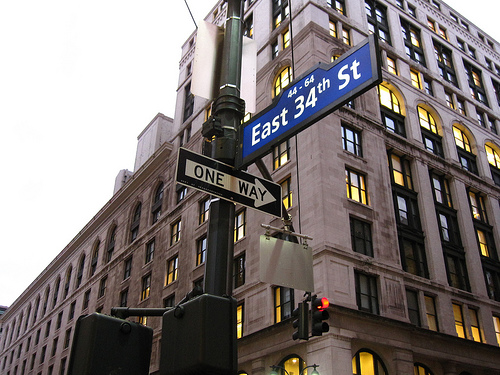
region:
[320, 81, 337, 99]
the sign is blue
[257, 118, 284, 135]
the word is white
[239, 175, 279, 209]
the arrow is white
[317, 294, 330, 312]
the light is red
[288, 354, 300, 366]
the light is on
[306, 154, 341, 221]
the building is tan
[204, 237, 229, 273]
the pole is black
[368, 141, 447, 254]
the building has a lot of windows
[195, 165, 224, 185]
the word is black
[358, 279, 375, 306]
the blind is closed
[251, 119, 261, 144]
white letter on sign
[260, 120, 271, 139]
white letter on sign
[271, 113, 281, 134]
white letter on sign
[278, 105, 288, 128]
white letter on sign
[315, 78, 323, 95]
white letter on sign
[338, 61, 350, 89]
white letter on sign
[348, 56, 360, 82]
white letter on sign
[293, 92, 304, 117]
white number on sign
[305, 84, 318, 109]
white number on sign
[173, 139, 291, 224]
The sign is black and white.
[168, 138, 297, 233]
The arrow on the sign is white.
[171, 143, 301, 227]
The sign is rectangulare.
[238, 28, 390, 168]
The sign is blue and white.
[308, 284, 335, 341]
The traffic light is red.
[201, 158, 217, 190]
The letter is black.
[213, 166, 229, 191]
The letter is black.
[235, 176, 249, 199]
The letter is black.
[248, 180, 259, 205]
The letter is black.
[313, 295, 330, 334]
traffic light on the wire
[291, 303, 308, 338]
traffic light on the wire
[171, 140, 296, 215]
traffic sign on the pole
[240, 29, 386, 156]
street sign on the pole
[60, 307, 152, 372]
back of the crosswalk light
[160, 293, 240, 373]
back of the cross walk light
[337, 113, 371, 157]
window on the buiding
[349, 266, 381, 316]
window on the buiding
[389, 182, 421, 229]
window on the buiding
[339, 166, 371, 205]
a window on building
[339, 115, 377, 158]
a window on building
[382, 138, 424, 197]
a window on building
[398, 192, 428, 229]
a window on building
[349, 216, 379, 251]
a window on building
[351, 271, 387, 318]
a window on building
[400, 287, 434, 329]
a window on building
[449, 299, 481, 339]
a window on building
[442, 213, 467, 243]
a window on building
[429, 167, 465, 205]
a window on building